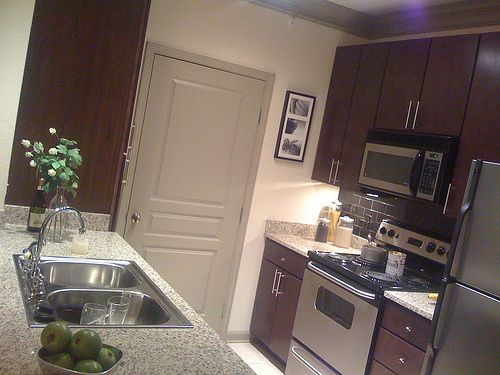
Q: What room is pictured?
A: It is a kitchen.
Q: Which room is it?
A: It is a kitchen.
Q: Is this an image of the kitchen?
A: Yes, it is showing the kitchen.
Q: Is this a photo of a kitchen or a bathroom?
A: It is showing a kitchen.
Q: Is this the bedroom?
A: No, it is the kitchen.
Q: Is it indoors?
A: Yes, it is indoors.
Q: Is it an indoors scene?
A: Yes, it is indoors.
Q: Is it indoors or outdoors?
A: It is indoors.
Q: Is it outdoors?
A: No, it is indoors.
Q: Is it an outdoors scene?
A: No, it is indoors.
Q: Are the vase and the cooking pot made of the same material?
A: No, the vase is made of glass and the cooking pot is made of metal.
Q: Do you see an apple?
A: Yes, there is an apple.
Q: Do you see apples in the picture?
A: Yes, there is an apple.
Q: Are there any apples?
A: Yes, there is an apple.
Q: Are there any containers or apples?
A: Yes, there is an apple.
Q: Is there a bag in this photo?
A: No, there are no bags.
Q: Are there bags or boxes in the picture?
A: No, there are no bags or boxes.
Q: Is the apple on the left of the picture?
A: Yes, the apple is on the left of the image.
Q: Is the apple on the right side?
A: No, the apple is on the left of the image.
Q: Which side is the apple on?
A: The apple is on the left of the image.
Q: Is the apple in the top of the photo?
A: No, the apple is in the bottom of the image.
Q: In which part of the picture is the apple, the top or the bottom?
A: The apple is in the bottom of the image.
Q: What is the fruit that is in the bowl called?
A: The fruit is an apple.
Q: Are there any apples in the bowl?
A: Yes, there is an apple in the bowl.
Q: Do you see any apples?
A: Yes, there is an apple.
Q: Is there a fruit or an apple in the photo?
A: Yes, there is an apple.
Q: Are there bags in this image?
A: No, there are no bags.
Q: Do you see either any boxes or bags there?
A: No, there are no bags or boxes.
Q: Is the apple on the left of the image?
A: Yes, the apple is on the left of the image.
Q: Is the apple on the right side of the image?
A: No, the apple is on the left of the image.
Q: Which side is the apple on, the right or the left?
A: The apple is on the left of the image.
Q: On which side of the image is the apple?
A: The apple is on the left of the image.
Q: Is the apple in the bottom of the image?
A: Yes, the apple is in the bottom of the image.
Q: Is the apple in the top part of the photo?
A: No, the apple is in the bottom of the image.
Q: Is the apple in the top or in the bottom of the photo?
A: The apple is in the bottom of the image.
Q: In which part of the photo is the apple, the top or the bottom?
A: The apple is in the bottom of the image.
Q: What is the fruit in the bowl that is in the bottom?
A: The fruit is an apple.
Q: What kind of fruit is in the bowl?
A: The fruit is an apple.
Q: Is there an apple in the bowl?
A: Yes, there is an apple in the bowl.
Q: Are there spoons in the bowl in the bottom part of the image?
A: No, there is an apple in the bowl.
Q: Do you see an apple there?
A: Yes, there is an apple.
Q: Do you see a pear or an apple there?
A: Yes, there is an apple.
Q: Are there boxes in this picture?
A: No, there are no boxes.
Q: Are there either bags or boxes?
A: No, there are no boxes or bags.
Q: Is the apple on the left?
A: Yes, the apple is on the left of the image.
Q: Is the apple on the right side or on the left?
A: The apple is on the left of the image.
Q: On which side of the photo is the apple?
A: The apple is on the left of the image.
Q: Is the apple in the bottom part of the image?
A: Yes, the apple is in the bottom of the image.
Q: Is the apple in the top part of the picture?
A: No, the apple is in the bottom of the image.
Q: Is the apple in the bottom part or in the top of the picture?
A: The apple is in the bottom of the image.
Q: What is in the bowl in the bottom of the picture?
A: The apple is in the bowl.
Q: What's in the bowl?
A: The apple is in the bowl.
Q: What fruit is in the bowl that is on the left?
A: The fruit is an apple.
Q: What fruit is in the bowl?
A: The fruit is an apple.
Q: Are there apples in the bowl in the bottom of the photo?
A: Yes, there is an apple in the bowl.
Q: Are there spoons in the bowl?
A: No, there is an apple in the bowl.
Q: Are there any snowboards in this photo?
A: No, there are no snowboards.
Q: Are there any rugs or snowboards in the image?
A: No, there are no snowboards or rugs.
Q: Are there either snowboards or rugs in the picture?
A: No, there are no snowboards or rugs.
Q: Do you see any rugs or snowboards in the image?
A: No, there are no snowboards or rugs.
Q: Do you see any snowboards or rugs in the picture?
A: No, there are no snowboards or rugs.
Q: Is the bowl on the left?
A: Yes, the bowl is on the left of the image.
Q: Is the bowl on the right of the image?
A: No, the bowl is on the left of the image.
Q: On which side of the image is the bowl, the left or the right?
A: The bowl is on the left of the image.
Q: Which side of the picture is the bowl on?
A: The bowl is on the left of the image.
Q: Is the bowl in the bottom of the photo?
A: Yes, the bowl is in the bottom of the image.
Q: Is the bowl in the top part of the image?
A: No, the bowl is in the bottom of the image.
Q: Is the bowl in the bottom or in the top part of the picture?
A: The bowl is in the bottom of the image.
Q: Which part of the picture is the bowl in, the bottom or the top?
A: The bowl is in the bottom of the image.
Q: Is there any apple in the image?
A: Yes, there is an apple.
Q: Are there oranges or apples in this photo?
A: Yes, there is an apple.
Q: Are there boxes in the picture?
A: No, there are no boxes.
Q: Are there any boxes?
A: No, there are no boxes.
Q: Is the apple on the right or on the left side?
A: The apple is on the left of the image.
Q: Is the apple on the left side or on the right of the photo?
A: The apple is on the left of the image.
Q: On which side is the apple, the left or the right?
A: The apple is on the left of the image.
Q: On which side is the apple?
A: The apple is on the left of the image.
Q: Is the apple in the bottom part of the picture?
A: Yes, the apple is in the bottom of the image.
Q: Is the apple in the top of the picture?
A: No, the apple is in the bottom of the image.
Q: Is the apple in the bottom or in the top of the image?
A: The apple is in the bottom of the image.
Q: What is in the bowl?
A: The apple is in the bowl.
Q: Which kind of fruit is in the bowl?
A: The fruit is an apple.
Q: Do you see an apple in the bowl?
A: Yes, there is an apple in the bowl.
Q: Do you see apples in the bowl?
A: Yes, there is an apple in the bowl.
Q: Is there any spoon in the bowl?
A: No, there is an apple in the bowl.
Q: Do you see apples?
A: Yes, there is an apple.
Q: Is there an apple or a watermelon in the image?
A: Yes, there is an apple.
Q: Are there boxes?
A: No, there are no boxes.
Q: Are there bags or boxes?
A: No, there are no boxes or bags.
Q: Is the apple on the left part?
A: Yes, the apple is on the left of the image.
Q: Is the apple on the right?
A: No, the apple is on the left of the image.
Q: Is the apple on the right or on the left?
A: The apple is on the left of the image.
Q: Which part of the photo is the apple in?
A: The apple is on the left of the image.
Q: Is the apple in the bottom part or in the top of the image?
A: The apple is in the bottom of the image.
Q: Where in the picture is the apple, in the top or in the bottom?
A: The apple is in the bottom of the image.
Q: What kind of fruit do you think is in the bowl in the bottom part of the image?
A: The fruit is an apple.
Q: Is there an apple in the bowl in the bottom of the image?
A: Yes, there is an apple in the bowl.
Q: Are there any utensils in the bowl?
A: No, there is an apple in the bowl.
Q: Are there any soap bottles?
A: No, there are no soap bottles.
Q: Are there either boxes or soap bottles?
A: No, there are no soap bottles or boxes.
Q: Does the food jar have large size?
A: Yes, the jar is large.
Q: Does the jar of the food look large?
A: Yes, the jar is large.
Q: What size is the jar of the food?
A: The jar is large.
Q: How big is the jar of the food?
A: The jar is large.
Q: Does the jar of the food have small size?
A: No, the jar is large.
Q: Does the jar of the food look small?
A: No, the jar is large.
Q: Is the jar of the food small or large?
A: The jar is large.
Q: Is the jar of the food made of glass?
A: Yes, the jar is made of glass.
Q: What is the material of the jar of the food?
A: The jar is made of glass.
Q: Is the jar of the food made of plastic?
A: No, the jar is made of glass.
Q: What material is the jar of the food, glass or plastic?
A: The jar is made of glass.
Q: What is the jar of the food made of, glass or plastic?
A: The jar is made of glass.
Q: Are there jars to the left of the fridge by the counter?
A: Yes, there is a jar to the left of the freezer.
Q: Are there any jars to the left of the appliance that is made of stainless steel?
A: Yes, there is a jar to the left of the freezer.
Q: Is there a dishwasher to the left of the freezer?
A: No, there is a jar to the left of the freezer.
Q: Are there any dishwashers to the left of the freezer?
A: No, there is a jar to the left of the freezer.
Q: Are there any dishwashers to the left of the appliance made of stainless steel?
A: No, there is a jar to the left of the freezer.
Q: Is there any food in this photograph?
A: Yes, there is food.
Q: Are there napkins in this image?
A: No, there are no napkins.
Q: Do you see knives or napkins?
A: No, there are no napkins or knives.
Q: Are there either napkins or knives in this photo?
A: No, there are no napkins or knives.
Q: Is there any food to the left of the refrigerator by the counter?
A: Yes, there is food to the left of the freezer.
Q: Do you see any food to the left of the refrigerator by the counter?
A: Yes, there is food to the left of the freezer.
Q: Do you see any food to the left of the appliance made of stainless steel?
A: Yes, there is food to the left of the freezer.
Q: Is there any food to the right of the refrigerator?
A: No, the food is to the left of the refrigerator.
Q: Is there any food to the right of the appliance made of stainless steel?
A: No, the food is to the left of the refrigerator.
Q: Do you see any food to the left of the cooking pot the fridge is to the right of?
A: Yes, there is food to the left of the cooking pot.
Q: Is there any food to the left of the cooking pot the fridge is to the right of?
A: Yes, there is food to the left of the cooking pot.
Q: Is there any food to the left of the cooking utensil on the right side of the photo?
A: Yes, there is food to the left of the cooking pot.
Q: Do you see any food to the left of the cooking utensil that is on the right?
A: Yes, there is food to the left of the cooking pot.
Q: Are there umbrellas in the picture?
A: No, there are no umbrellas.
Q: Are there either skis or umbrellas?
A: No, there are no umbrellas or skis.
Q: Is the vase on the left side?
A: Yes, the vase is on the left of the image.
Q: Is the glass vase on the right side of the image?
A: No, the vase is on the left of the image.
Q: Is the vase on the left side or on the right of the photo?
A: The vase is on the left of the image.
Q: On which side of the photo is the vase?
A: The vase is on the left of the image.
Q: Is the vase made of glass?
A: Yes, the vase is made of glass.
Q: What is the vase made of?
A: The vase is made of glass.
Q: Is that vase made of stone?
A: No, the vase is made of glass.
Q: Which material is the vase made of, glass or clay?
A: The vase is made of glass.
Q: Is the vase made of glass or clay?
A: The vase is made of glass.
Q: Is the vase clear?
A: Yes, the vase is clear.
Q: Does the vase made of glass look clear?
A: Yes, the vase is clear.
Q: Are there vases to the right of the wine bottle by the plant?
A: Yes, there is a vase to the right of the wine bottle.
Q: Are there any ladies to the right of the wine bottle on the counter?
A: No, there is a vase to the right of the wine bottle.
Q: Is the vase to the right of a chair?
A: No, the vase is to the right of the wine bottle.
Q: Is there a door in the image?
A: Yes, there is a door.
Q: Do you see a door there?
A: Yes, there is a door.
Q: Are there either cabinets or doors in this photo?
A: Yes, there is a door.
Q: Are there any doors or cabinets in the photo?
A: Yes, there is a door.